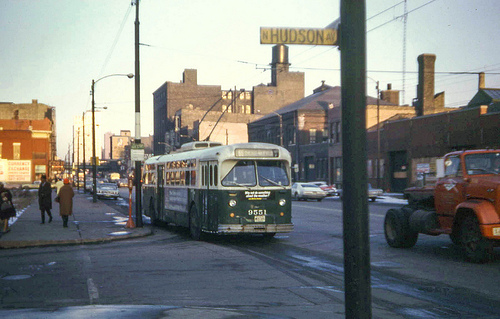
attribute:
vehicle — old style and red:
[158, 125, 291, 319]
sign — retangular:
[235, 9, 365, 76]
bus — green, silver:
[118, 139, 317, 251]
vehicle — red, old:
[375, 161, 499, 258]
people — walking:
[24, 166, 84, 213]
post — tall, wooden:
[100, 62, 153, 81]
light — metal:
[56, 60, 113, 188]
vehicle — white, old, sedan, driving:
[282, 174, 319, 195]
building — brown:
[135, 54, 325, 161]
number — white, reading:
[238, 193, 288, 233]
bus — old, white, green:
[125, 137, 286, 243]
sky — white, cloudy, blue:
[18, 16, 209, 115]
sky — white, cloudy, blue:
[17, 14, 201, 135]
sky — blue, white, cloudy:
[122, 13, 282, 117]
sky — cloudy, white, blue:
[135, 13, 255, 82]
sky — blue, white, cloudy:
[365, 24, 460, 94]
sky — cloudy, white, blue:
[135, 13, 261, 75]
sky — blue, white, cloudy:
[15, 17, 145, 104]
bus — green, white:
[140, 130, 300, 226]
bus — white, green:
[202, 150, 311, 185]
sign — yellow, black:
[219, 10, 344, 65]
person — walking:
[26, 172, 63, 206]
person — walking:
[28, 164, 82, 210]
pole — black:
[118, 22, 164, 246]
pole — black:
[315, 26, 393, 316]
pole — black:
[81, 80, 105, 219]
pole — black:
[77, 131, 86, 191]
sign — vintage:
[254, 22, 361, 57]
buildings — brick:
[175, 52, 363, 202]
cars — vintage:
[247, 145, 336, 210]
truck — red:
[367, 126, 497, 271]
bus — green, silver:
[119, 129, 331, 276]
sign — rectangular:
[254, 25, 334, 69]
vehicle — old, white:
[293, 178, 325, 211]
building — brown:
[156, 69, 304, 143]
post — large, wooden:
[93, 80, 120, 210]